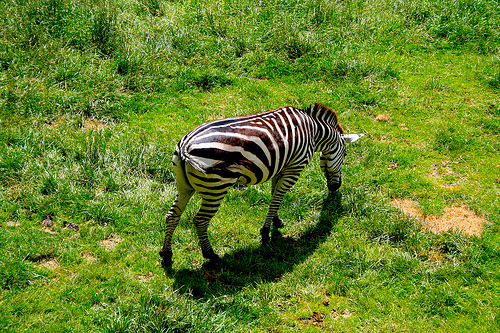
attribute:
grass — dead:
[19, 220, 139, 307]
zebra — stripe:
[147, 90, 363, 268]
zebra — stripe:
[140, 92, 352, 255]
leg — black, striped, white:
[257, 170, 300, 246]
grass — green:
[324, 180, 356, 207]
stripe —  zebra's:
[191, 147, 253, 166]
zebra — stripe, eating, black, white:
[155, 97, 363, 281]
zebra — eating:
[282, 98, 371, 206]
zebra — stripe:
[154, 100, 367, 269]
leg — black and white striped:
[192, 187, 223, 267]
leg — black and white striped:
[256, 160, 309, 240]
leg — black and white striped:
[159, 190, 184, 267]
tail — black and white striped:
[171, 138, 207, 189]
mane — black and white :
[301, 100, 345, 130]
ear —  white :
[340, 130, 364, 150]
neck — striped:
[307, 110, 334, 153]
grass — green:
[301, 186, 408, 284]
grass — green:
[295, 174, 405, 295]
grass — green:
[307, 186, 414, 292]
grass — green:
[43, 42, 163, 199]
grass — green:
[297, 188, 407, 331]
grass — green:
[319, 187, 404, 252]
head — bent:
[315, 127, 369, 194]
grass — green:
[124, 69, 405, 330]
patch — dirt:
[382, 189, 489, 247]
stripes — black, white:
[232, 120, 299, 165]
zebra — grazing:
[144, 89, 371, 281]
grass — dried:
[395, 196, 487, 241]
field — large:
[4, 4, 494, 327]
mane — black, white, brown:
[295, 96, 345, 134]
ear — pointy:
[339, 124, 371, 153]